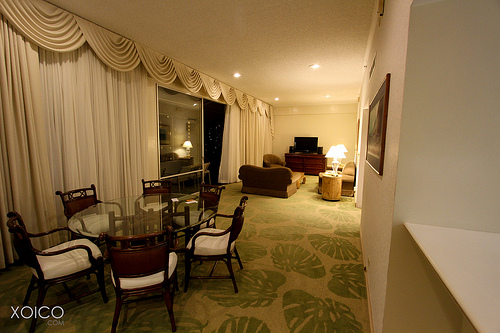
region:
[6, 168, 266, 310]
Round glass table and chairs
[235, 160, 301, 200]
A brown couch with two humps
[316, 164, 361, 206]
A round end table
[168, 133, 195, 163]
Reflection of a light on the glass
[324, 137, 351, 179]
Two lamps are on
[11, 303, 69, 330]
White letters of a website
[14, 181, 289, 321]
Brown chairs with white cushions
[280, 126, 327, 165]
Tv sits on a stand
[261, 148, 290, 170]
A brown chair in the corner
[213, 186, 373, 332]
Large leaf pattern on floor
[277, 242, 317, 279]
a green leaf pattern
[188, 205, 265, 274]
a wooden chair with a white seat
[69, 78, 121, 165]
white silk curtains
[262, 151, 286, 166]
a brown chair in the corner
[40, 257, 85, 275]
a white cushion on the chair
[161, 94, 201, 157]
a glass sliding door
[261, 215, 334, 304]
green and beige carpet on the floor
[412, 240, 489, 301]
the edge of a white counter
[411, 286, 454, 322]
an inset in the wall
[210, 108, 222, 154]
the black night sky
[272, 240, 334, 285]
a green leaf pattern on the carpet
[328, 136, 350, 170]
lamps on the side table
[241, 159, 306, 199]
a brown camel back sofa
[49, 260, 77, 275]
white cushion in the chair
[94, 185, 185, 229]
a glass top table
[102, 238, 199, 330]
a wooden chair with a white seat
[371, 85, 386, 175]
a painting hanging on the wall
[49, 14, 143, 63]
a beige festooned window valance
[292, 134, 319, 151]
a flat screen tv on a chest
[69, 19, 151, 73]
drapping over top curtains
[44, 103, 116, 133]
beige curtains on windows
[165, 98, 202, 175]
lamp reflection in window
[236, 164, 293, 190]
back of greenish couch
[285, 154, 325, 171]
maple wood dresser drawers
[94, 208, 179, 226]
large round glass table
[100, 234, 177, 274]
back of burgandy chair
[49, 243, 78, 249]
white cushion in chair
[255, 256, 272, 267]
teal carpet on floor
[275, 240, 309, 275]
green design on carpet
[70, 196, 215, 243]
Round glass table top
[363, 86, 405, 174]
A picture hangs on the wall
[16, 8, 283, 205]
A long row of curtains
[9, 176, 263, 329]
Several brown chairs with white seats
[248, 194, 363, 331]
Large green leaf pattern on floor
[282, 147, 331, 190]
Wooden brown tv stand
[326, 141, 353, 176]
Two table lamps are on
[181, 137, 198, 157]
Reflection of lamp in glass